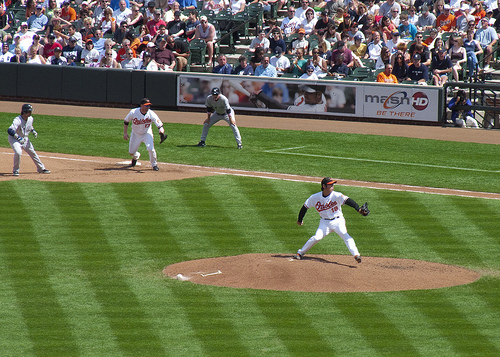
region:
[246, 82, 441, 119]
Advertisement board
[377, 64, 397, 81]
Man wearing orange Tees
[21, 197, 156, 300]
Maintained lawn grass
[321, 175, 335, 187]
Orange and blue cap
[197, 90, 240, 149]
Man resting hand on his thigh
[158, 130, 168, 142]
Man wearing catching gloves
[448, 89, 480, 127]
Man holding camera on his hand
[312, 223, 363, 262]
Man wearing White trouser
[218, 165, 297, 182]
Marked chalk lines on ground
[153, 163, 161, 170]
Man wearing black shoe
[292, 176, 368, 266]
Baseball pitches for orioles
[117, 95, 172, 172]
Orioles first base man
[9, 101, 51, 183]
Runner taking lead off first base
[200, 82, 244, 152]
First base coach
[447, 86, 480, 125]
Photogrpaher in blue sitting against railing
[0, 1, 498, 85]
Fans in their seats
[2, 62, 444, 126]
Wall dividing field from stands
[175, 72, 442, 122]
Advert for masnHD television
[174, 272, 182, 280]
Chalk bag for pitcher's grip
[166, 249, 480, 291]
Dirt pitching mound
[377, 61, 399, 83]
A person wearing a orange shirt.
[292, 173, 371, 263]
A baseball player on the field.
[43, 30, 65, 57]
A person wearing a red shirt.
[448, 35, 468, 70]
A person wearing a black shirt.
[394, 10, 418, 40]
A person wearing a blue shirt.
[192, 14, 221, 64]
A person wearing a hat.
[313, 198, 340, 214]
The team name on a uniform.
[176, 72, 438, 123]
A sign on the wall.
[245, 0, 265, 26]
A empty seat in the bleachers.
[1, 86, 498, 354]
The baseball field with players on it.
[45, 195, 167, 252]
The grass is green with stripes.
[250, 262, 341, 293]
The dirt is brown.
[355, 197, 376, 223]
The pitcher is wearing a glove.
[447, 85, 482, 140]
The man is taking a picture.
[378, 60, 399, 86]
The mans shirt is orange.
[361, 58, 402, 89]
Orange is the color of the mans shirt.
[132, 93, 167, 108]
The player has a hit with red on it.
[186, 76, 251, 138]
The teammate is crouching down.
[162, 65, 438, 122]
The billboard in the background is for MASN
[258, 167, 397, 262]
The man is throwing the ball.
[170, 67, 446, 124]
sign on wall for MASN HD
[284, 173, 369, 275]
Pitcher in white and black uniform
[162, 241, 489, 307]
Pitchers mound on baseball field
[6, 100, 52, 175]
Baseball player wearing helmet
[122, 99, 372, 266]
two baseball players wearing gloves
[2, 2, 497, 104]
spectators in the stands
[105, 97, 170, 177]
man playing first base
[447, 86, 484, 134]
man filming baseball game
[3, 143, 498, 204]
base line on field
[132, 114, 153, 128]
red letters on baseball jersey